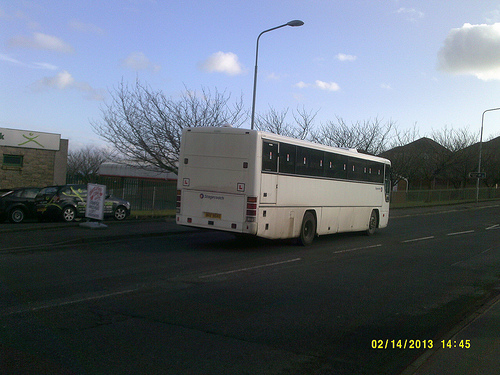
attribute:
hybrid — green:
[35, 181, 133, 224]